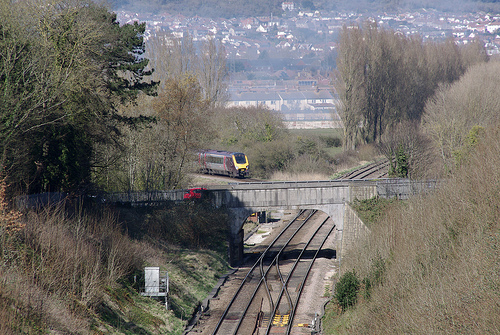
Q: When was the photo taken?
A: Daytime.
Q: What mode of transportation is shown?
A: Train.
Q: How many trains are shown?
A: One.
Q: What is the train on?
A: Tracks.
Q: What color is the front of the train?
A: Black and yellow.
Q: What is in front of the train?
A: Bridge.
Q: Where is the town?
A: Background.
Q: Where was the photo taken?
A: At a train crossing.